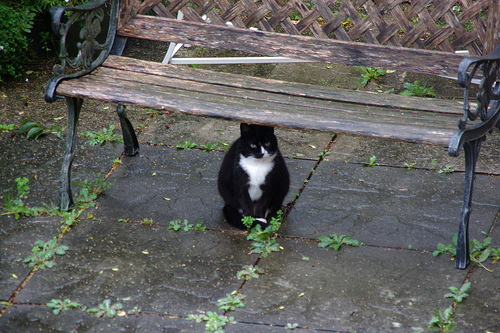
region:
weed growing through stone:
[317, 231, 359, 251]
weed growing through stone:
[246, 238, 283, 258]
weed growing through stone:
[232, 260, 267, 285]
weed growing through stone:
[216, 291, 246, 311]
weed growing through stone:
[91, 298, 123, 321]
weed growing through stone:
[46, 297, 79, 317]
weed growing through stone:
[443, 280, 475, 305]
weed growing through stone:
[429, 239, 454, 259]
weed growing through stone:
[172, 136, 196, 151]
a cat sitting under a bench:
[211, 116, 299, 237]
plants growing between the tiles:
[3, 170, 140, 323]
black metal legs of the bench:
[50, 7, 147, 215]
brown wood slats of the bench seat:
[111, 69, 435, 132]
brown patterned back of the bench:
[120, 0, 476, 75]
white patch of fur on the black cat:
[236, 148, 278, 203]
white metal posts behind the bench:
[151, 9, 496, 104]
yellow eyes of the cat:
[243, 135, 279, 156]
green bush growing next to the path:
[0, 3, 70, 75]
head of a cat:
[243, 113, 283, 161]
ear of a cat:
[235, 122, 260, 137]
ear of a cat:
[260, 119, 285, 131]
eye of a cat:
[243, 137, 259, 149]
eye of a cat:
[265, 135, 279, 152]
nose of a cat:
[257, 145, 268, 160]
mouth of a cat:
[254, 153, 266, 164]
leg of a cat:
[234, 201, 256, 229]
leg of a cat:
[255, 207, 274, 234]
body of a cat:
[193, 152, 305, 252]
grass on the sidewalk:
[187, 275, 244, 330]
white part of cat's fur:
[240, 150, 260, 188]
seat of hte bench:
[99, 60, 466, 142]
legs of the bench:
[30, 120, 134, 214]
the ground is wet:
[303, 255, 409, 297]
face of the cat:
[241, 118, 283, 162]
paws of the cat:
[228, 215, 280, 235]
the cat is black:
[222, 188, 248, 222]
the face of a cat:
[231, 99, 313, 171]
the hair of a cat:
[230, 118, 313, 180]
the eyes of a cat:
[239, 133, 295, 161]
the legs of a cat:
[228, 148, 323, 253]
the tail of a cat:
[211, 175, 276, 271]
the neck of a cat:
[226, 125, 296, 175]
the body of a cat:
[206, 105, 312, 225]